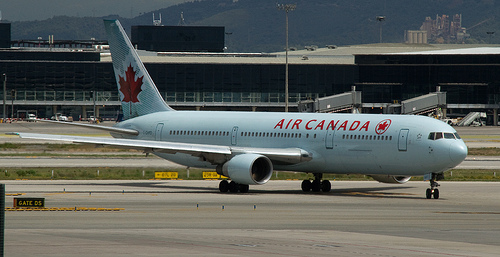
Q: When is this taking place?
A: Daytime.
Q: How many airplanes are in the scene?
A: One.